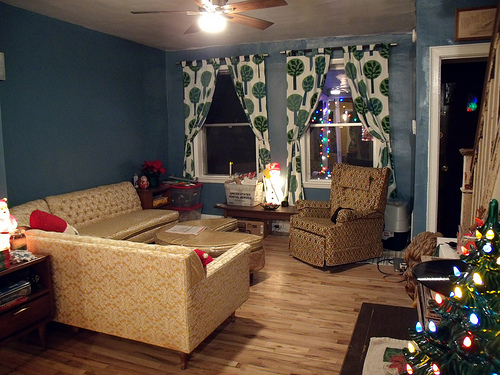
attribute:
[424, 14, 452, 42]
wall — blue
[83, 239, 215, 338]
couch — leather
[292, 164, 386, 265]
chair — two-toned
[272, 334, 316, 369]
floor — hardwood, wooden